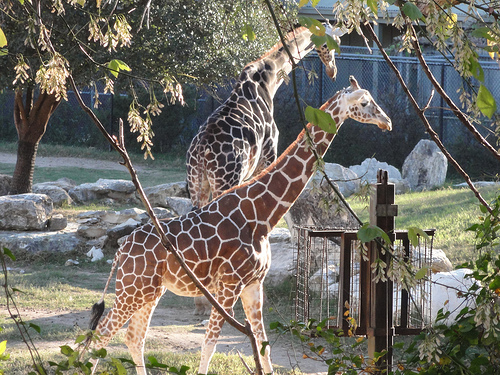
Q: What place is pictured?
A: It is a pasture.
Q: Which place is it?
A: It is a pasture.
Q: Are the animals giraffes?
A: Yes, all the animals are giraffes.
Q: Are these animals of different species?
A: No, all the animals are giraffes.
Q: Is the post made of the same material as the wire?
A: No, the post is made of wood and the wire is made of metal.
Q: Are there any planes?
A: No, there are no planes.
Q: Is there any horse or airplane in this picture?
A: No, there are no airplanes or horses.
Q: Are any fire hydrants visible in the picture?
A: No, there are no fire hydrants.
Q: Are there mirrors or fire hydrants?
A: No, there are no fire hydrants or mirrors.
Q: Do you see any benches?
A: No, there are no benches.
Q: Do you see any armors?
A: No, there are no armors.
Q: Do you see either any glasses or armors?
A: No, there are no armors or glasses.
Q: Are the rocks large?
A: Yes, the rocks are large.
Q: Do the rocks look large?
A: Yes, the rocks are large.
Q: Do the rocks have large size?
A: Yes, the rocks are large.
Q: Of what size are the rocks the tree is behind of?
A: The rocks are large.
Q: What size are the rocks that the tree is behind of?
A: The rocks are large.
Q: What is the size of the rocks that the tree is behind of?
A: The rocks are large.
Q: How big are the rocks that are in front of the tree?
A: The rocks are large.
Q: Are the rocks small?
A: No, the rocks are large.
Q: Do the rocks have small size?
A: No, the rocks are large.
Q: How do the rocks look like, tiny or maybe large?
A: The rocks are large.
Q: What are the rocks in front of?
A: The rocks are in front of the tree.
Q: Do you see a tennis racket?
A: No, there are no rackets.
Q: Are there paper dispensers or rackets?
A: No, there are no rackets or paper dispensers.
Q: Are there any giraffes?
A: Yes, there is a giraffe.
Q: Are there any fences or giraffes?
A: Yes, there is a giraffe.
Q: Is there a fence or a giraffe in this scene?
A: Yes, there is a giraffe.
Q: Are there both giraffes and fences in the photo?
A: Yes, there are both a giraffe and a fence.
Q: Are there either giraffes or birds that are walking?
A: Yes, the giraffe is walking.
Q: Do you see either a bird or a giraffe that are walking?
A: Yes, the giraffe is walking.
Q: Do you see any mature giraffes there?
A: Yes, there is a mature giraffe.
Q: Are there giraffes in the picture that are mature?
A: Yes, there is a giraffe that is mature.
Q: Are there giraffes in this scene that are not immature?
A: Yes, there is an mature giraffe.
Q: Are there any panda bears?
A: No, there are no panda bears.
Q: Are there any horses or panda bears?
A: No, there are no panda bears or horses.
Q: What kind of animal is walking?
A: The animal is a giraffe.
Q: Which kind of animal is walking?
A: The animal is a giraffe.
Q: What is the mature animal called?
A: The animal is a giraffe.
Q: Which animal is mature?
A: The animal is a giraffe.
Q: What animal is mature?
A: The animal is a giraffe.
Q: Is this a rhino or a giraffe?
A: This is a giraffe.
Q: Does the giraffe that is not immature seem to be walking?
A: Yes, the giraffe is walking.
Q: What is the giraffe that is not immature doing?
A: The giraffe is walking.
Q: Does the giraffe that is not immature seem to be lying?
A: No, the giraffe is walking.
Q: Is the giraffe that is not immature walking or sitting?
A: The giraffe is walking.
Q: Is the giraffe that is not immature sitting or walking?
A: The giraffe is walking.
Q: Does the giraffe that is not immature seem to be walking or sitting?
A: The giraffe is walking.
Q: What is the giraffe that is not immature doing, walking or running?
A: The giraffe is walking.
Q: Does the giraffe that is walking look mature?
A: Yes, the giraffe is mature.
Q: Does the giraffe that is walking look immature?
A: No, the giraffe is mature.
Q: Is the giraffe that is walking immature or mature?
A: The giraffe is mature.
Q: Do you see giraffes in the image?
A: Yes, there is a giraffe.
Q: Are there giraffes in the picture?
A: Yes, there is a giraffe.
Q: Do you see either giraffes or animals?
A: Yes, there is a giraffe.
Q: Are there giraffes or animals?
A: Yes, there is a giraffe.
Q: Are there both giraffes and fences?
A: Yes, there are both a giraffe and a fence.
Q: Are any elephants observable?
A: No, there are no elephants.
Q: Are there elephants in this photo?
A: No, there are no elephants.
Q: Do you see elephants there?
A: No, there are no elephants.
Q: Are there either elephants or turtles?
A: No, there are no elephants or turtles.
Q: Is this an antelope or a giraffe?
A: This is a giraffe.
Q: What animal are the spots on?
A: The spots are on the giraffe.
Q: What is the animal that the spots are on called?
A: The animal is a giraffe.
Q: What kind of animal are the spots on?
A: The spots are on the giraffe.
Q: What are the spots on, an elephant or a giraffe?
A: The spots are on a giraffe.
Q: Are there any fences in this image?
A: Yes, there is a fence.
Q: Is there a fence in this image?
A: Yes, there is a fence.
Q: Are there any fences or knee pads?
A: Yes, there is a fence.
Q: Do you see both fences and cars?
A: No, there is a fence but no cars.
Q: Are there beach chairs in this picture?
A: No, there are no beach chairs.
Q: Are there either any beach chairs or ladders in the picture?
A: No, there are no beach chairs or ladders.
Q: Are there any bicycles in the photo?
A: No, there are no bicycles.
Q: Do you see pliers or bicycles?
A: No, there are no bicycles or pliers.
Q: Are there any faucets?
A: No, there are no faucets.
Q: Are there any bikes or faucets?
A: No, there are no faucets or bikes.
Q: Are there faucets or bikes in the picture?
A: No, there are no faucets or bikes.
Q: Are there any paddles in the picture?
A: No, there are no paddles.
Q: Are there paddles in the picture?
A: No, there are no paddles.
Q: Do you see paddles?
A: No, there are no paddles.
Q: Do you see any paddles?
A: No, there are no paddles.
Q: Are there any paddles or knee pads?
A: No, there are no paddles or knee pads.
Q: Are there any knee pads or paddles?
A: No, there are no paddles or knee pads.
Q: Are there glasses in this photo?
A: No, there are no glasses.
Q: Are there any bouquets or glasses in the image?
A: No, there are no glasses or bouquets.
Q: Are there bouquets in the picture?
A: No, there are no bouquets.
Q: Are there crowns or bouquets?
A: No, there are no bouquets or crowns.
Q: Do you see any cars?
A: No, there are no cars.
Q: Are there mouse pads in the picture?
A: No, there are no mouse pads.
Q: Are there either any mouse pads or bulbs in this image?
A: No, there are no mouse pads or bulbs.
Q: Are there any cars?
A: No, there are no cars.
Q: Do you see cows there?
A: No, there are no cows.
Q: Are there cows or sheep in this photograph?
A: No, there are no cows or sheep.